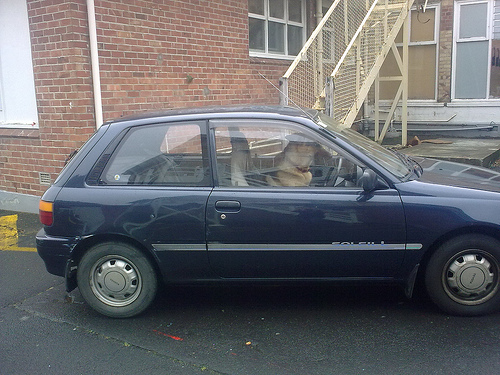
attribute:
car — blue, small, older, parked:
[34, 104, 499, 318]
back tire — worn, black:
[76, 243, 156, 317]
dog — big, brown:
[259, 134, 331, 187]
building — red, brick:
[0, 0, 498, 214]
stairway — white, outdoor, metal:
[282, 3, 413, 145]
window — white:
[0, 2, 42, 135]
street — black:
[2, 211, 500, 373]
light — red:
[40, 208, 52, 223]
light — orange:
[38, 200, 53, 211]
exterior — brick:
[1, 0, 500, 196]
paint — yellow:
[2, 212, 37, 255]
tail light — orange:
[38, 200, 53, 225]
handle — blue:
[215, 198, 242, 213]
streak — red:
[153, 324, 183, 342]